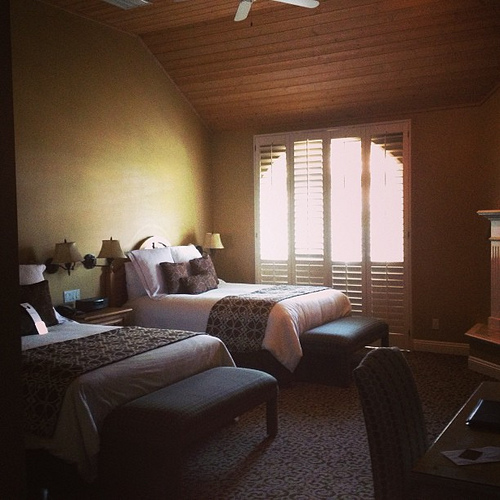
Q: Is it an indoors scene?
A: Yes, it is indoors.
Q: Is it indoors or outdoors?
A: It is indoors.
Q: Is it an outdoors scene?
A: No, it is indoors.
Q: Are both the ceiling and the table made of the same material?
A: Yes, both the ceiling and the table are made of wood.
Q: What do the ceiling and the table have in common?
A: The material, both the ceiling and the table are wooden.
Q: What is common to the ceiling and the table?
A: The material, both the ceiling and the table are wooden.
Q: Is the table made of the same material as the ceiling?
A: Yes, both the table and the ceiling are made of wood.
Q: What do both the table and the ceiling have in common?
A: The material, both the table and the ceiling are wooden.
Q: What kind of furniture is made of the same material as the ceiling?
A: The table is made of the same material as the ceiling.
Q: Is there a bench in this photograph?
A: Yes, there is a bench.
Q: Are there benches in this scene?
A: Yes, there is a bench.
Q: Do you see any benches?
A: Yes, there is a bench.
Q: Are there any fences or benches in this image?
A: Yes, there is a bench.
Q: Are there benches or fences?
A: Yes, there is a bench.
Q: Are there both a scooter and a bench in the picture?
A: No, there is a bench but no scooters.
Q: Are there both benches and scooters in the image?
A: No, there is a bench but no scooters.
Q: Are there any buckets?
A: No, there are no buckets.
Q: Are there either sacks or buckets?
A: No, there are no buckets or sacks.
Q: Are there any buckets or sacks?
A: No, there are no buckets or sacks.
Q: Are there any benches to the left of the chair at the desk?
A: Yes, there is a bench to the left of the chair.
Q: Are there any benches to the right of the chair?
A: No, the bench is to the left of the chair.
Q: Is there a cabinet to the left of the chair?
A: No, there is a bench to the left of the chair.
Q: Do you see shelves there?
A: No, there are no shelves.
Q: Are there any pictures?
A: No, there are no pictures.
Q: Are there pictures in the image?
A: No, there are no pictures.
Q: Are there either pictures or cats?
A: No, there are no pictures or cats.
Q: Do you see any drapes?
A: No, there are no drapes.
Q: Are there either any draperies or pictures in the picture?
A: No, there are no draperies or pictures.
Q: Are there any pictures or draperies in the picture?
A: No, there are no draperies or pictures.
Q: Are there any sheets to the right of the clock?
A: Yes, there is a sheet to the right of the clock.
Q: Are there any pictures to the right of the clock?
A: No, there is a sheet to the right of the clock.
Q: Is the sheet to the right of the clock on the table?
A: Yes, the sheet is to the right of the clock.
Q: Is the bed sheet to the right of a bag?
A: No, the bed sheet is to the right of the clock.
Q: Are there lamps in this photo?
A: Yes, there is a lamp.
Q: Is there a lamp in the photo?
A: Yes, there is a lamp.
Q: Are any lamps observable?
A: Yes, there is a lamp.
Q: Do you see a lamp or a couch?
A: Yes, there is a lamp.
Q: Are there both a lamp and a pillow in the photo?
A: Yes, there are both a lamp and a pillow.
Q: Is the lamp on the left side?
A: Yes, the lamp is on the left of the image.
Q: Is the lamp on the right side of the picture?
A: No, the lamp is on the left of the image.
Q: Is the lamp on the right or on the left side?
A: The lamp is on the left of the image.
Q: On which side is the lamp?
A: The lamp is on the left of the image.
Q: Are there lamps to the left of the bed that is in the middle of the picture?
A: Yes, there is a lamp to the left of the bed.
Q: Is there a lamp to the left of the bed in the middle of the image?
A: Yes, there is a lamp to the left of the bed.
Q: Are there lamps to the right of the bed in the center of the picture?
A: No, the lamp is to the left of the bed.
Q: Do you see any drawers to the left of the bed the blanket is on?
A: No, there is a lamp to the left of the bed.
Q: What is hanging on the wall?
A: The lamp is hanging on the wall.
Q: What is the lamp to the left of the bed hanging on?
A: The lamp is hanging on the wall.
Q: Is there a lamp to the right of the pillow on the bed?
A: No, the lamp is to the left of the pillow.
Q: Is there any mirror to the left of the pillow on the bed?
A: No, there is a lamp to the left of the pillow.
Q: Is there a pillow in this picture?
A: Yes, there is a pillow.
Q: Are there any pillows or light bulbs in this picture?
A: Yes, there is a pillow.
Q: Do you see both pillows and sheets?
A: Yes, there are both a pillow and a sheet.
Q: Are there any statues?
A: No, there are no statues.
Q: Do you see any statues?
A: No, there are no statues.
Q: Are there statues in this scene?
A: No, there are no statues.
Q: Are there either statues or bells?
A: No, there are no statues or bells.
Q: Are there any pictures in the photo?
A: No, there are no pictures.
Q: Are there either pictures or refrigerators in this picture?
A: No, there are no pictures or refrigerators.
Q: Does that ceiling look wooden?
A: Yes, the ceiling is wooden.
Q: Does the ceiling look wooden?
A: Yes, the ceiling is wooden.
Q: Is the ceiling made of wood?
A: Yes, the ceiling is made of wood.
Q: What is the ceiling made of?
A: The ceiling is made of wood.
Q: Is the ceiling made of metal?
A: No, the ceiling is made of wood.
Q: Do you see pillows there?
A: Yes, there is a pillow.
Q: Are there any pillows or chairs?
A: Yes, there is a pillow.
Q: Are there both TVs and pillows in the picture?
A: No, there is a pillow but no televisions.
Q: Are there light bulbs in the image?
A: No, there are no light bulbs.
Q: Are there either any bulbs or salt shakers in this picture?
A: No, there are no bulbs or salt shakers.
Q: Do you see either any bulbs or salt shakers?
A: No, there are no bulbs or salt shakers.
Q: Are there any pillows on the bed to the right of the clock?
A: Yes, there is a pillow on the bed.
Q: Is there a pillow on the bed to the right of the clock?
A: Yes, there is a pillow on the bed.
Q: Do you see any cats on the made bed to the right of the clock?
A: No, there is a pillow on the bed.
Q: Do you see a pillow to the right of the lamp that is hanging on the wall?
A: Yes, there is a pillow to the right of the lamp.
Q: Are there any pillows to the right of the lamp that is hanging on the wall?
A: Yes, there is a pillow to the right of the lamp.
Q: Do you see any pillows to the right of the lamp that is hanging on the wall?
A: Yes, there is a pillow to the right of the lamp.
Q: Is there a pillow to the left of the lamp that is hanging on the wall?
A: No, the pillow is to the right of the lamp.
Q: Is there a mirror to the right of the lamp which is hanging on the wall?
A: No, there is a pillow to the right of the lamp.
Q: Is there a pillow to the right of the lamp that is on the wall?
A: Yes, there is a pillow to the right of the lamp.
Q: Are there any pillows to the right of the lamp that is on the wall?
A: Yes, there is a pillow to the right of the lamp.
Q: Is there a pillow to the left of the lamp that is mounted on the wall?
A: No, the pillow is to the right of the lamp.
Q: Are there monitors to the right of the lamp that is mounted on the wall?
A: No, there is a pillow to the right of the lamp.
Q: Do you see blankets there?
A: Yes, there is a blanket.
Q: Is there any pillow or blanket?
A: Yes, there is a blanket.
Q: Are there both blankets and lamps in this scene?
A: Yes, there are both a blanket and a lamp.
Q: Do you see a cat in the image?
A: No, there are no cats.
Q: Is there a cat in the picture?
A: No, there are no cats.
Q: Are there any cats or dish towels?
A: No, there are no cats or dish towels.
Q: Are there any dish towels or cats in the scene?
A: No, there are no cats or dish towels.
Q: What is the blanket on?
A: The blanket is on the bed.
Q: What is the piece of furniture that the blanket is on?
A: The piece of furniture is a bed.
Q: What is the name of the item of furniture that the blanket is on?
A: The piece of furniture is a bed.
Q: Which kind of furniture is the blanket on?
A: The blanket is on the bed.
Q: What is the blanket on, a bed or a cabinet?
A: The blanket is on a bed.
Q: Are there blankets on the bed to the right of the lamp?
A: Yes, there is a blanket on the bed.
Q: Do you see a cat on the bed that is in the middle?
A: No, there is a blanket on the bed.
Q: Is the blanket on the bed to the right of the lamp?
A: Yes, the blanket is on the bed.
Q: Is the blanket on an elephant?
A: No, the blanket is on the bed.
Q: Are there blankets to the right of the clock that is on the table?
A: Yes, there is a blanket to the right of the clock.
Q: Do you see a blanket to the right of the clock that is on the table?
A: Yes, there is a blanket to the right of the clock.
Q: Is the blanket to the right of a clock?
A: Yes, the blanket is to the right of a clock.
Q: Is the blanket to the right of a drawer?
A: No, the blanket is to the right of a clock.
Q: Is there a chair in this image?
A: Yes, there is a chair.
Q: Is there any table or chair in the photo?
A: Yes, there is a chair.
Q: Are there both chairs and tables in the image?
A: Yes, there are both a chair and a table.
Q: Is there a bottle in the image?
A: No, there are no bottles.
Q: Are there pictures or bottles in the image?
A: No, there are no bottles or pictures.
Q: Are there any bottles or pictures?
A: No, there are no bottles or pictures.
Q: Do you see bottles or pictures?
A: No, there are no bottles or pictures.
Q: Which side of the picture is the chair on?
A: The chair is on the right of the image.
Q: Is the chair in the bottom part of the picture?
A: Yes, the chair is in the bottom of the image.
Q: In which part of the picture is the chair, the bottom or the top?
A: The chair is in the bottom of the image.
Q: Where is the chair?
A: The chair is at the desk.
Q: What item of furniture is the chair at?
A: The chair is at the desk.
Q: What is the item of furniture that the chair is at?
A: The piece of furniture is a desk.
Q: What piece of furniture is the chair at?
A: The chair is at the desk.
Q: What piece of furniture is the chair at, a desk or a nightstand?
A: The chair is at a desk.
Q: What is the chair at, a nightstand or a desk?
A: The chair is at a desk.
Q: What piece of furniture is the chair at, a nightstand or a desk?
A: The chair is at a desk.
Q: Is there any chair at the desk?
A: Yes, there is a chair at the desk.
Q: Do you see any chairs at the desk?
A: Yes, there is a chair at the desk.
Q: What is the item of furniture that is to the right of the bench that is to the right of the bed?
A: The piece of furniture is a chair.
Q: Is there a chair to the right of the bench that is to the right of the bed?
A: Yes, there is a chair to the right of the bench.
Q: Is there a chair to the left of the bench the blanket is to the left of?
A: No, the chair is to the right of the bench.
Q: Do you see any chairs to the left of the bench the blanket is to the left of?
A: No, the chair is to the right of the bench.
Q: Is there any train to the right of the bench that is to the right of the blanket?
A: No, there is a chair to the right of the bench.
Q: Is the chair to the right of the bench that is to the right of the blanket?
A: Yes, the chair is to the right of the bench.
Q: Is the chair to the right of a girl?
A: No, the chair is to the right of the bench.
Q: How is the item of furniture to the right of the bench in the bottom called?
A: The piece of furniture is a chair.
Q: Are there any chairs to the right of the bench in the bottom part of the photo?
A: Yes, there is a chair to the right of the bench.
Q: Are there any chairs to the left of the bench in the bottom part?
A: No, the chair is to the right of the bench.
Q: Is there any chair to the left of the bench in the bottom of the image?
A: No, the chair is to the right of the bench.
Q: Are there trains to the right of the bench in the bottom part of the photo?
A: No, there is a chair to the right of the bench.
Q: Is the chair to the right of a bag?
A: No, the chair is to the right of a bench.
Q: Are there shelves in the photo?
A: No, there are no shelves.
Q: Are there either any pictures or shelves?
A: No, there are no shelves or pictures.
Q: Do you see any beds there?
A: Yes, there is a bed.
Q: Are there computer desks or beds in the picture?
A: Yes, there is a bed.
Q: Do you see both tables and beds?
A: Yes, there are both a bed and a table.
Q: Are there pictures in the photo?
A: No, there are no pictures.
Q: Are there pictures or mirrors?
A: No, there are no pictures or mirrors.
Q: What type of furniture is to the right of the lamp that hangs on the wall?
A: The piece of furniture is a bed.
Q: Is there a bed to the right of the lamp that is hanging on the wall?
A: Yes, there is a bed to the right of the lamp.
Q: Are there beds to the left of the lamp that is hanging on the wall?
A: No, the bed is to the right of the lamp.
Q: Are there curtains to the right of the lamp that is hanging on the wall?
A: No, there is a bed to the right of the lamp.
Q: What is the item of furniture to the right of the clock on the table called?
A: The piece of furniture is a bed.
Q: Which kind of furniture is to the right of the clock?
A: The piece of furniture is a bed.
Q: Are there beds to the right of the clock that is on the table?
A: Yes, there is a bed to the right of the clock.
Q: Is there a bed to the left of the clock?
A: No, the bed is to the right of the clock.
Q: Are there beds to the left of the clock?
A: No, the bed is to the right of the clock.